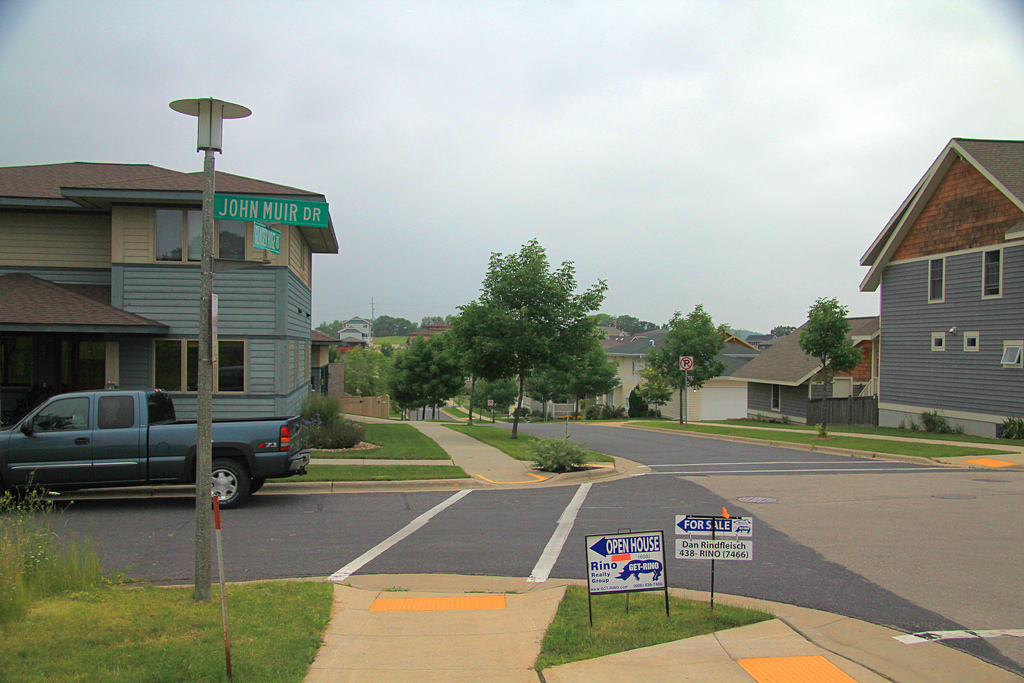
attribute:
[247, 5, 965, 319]
sky — gray, gloomy, cloudy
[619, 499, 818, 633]
sign — for sale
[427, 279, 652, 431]
trees — lining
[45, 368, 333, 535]
truck — dark grey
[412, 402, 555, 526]
walk — concrete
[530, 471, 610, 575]
line — white, long, painted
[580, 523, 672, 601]
sign — black, white, blue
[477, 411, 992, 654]
road — paved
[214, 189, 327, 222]
sign — green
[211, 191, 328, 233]
street sign — John Muir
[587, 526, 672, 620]
sign — open house sign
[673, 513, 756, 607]
sign — for sale sign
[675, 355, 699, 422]
sign — no parking sign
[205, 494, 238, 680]
post — orange and white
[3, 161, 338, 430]
house — tan and blue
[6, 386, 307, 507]
truck — blue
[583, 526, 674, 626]
sign — open house sign, blue and white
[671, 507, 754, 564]
sign — for sale sign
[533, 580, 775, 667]
grass — triangular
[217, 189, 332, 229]
sign — green, street sign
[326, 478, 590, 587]
lines — white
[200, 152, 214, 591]
pole — wooden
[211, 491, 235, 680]
pole — red on top, metal